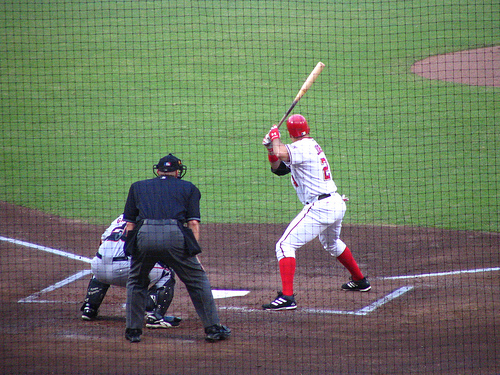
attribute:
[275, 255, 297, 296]
sock — red, tall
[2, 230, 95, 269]
line — white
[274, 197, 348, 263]
pants — white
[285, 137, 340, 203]
shirt — white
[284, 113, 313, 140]
helmet — red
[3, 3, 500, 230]
grass — green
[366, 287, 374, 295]
cleat — black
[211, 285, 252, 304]
home plate — base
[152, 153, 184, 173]
hat — black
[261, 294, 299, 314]
shoe — black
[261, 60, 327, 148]
bat — beige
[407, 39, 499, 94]
mound — pitcher's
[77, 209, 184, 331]
man — squatting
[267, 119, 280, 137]
hand — red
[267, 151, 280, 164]
wristband — red